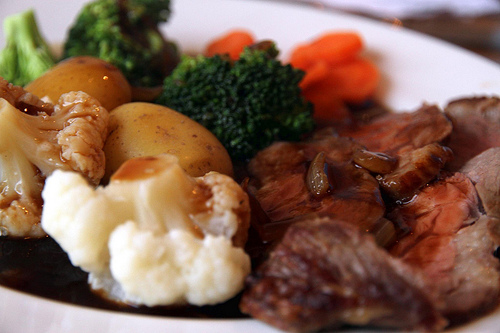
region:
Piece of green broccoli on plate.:
[202, 75, 257, 109]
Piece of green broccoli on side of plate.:
[107, 20, 145, 58]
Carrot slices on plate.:
[307, 38, 342, 113]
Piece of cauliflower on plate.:
[122, 239, 190, 299]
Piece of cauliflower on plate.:
[23, 129, 64, 165]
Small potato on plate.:
[128, 104, 200, 184]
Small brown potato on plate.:
[49, 67, 86, 97]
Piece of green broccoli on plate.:
[18, 20, 48, 52]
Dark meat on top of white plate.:
[273, 230, 308, 260]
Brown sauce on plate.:
[25, 241, 93, 327]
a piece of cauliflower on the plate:
[28, 150, 255, 310]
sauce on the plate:
[8, 240, 225, 325]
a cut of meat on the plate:
[231, 88, 494, 327]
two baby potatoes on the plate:
[36, 48, 232, 173]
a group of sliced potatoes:
[218, 9, 385, 114]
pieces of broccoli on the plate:
[68, 10, 308, 147]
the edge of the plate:
[272, 2, 470, 114]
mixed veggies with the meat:
[9, 5, 369, 320]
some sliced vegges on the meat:
[297, 135, 411, 195]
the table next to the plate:
[418, 5, 498, 52]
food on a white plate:
[7, 4, 495, 331]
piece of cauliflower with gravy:
[41, 139, 258, 309]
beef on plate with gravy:
[273, 124, 497, 331]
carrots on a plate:
[288, 18, 394, 121]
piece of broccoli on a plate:
[172, 43, 308, 148]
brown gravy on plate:
[6, 239, 59, 280]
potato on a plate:
[114, 100, 223, 159]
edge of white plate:
[375, 12, 470, 70]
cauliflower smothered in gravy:
[2, 74, 112, 174]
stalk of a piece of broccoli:
[0, 6, 47, 47]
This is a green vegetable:
[179, 64, 317, 133]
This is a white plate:
[11, 8, 498, 324]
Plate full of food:
[6, 9, 486, 324]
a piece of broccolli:
[45, 174, 253, 309]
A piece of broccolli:
[4, 71, 107, 246]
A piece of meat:
[256, 156, 374, 229]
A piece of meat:
[400, 202, 492, 305]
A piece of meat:
[259, 226, 410, 326]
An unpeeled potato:
[104, 99, 222, 176]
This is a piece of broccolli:
[85, 0, 166, 87]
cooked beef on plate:
[256, 221, 451, 332]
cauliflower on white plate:
[48, 162, 241, 297]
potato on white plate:
[109, 107, 230, 177]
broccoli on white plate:
[176, 41, 303, 151]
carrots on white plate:
[288, 30, 379, 125]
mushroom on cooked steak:
[314, 142, 388, 195]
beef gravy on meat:
[338, 169, 460, 259]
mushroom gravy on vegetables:
[4, 90, 238, 245]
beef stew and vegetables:
[5, 7, 497, 322]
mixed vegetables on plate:
[3, 13, 374, 309]